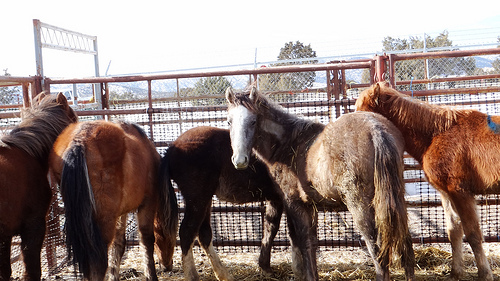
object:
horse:
[354, 82, 500, 281]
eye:
[251, 120, 257, 125]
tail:
[62, 143, 100, 281]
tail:
[369, 133, 408, 269]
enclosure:
[1, 22, 497, 249]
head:
[224, 81, 264, 170]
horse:
[153, 127, 283, 281]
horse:
[50, 119, 178, 281]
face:
[228, 107, 257, 167]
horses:
[0, 91, 79, 281]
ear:
[225, 86, 236, 104]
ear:
[372, 84, 380, 100]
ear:
[385, 82, 390, 88]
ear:
[57, 92, 69, 111]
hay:
[413, 245, 452, 281]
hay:
[316, 251, 376, 281]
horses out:
[248, 97, 394, 174]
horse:
[224, 84, 414, 281]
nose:
[232, 155, 248, 164]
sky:
[0, 0, 500, 79]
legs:
[288, 193, 415, 281]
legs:
[4, 224, 45, 281]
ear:
[249, 81, 258, 101]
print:
[487, 115, 500, 134]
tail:
[157, 154, 172, 236]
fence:
[0, 44, 500, 281]